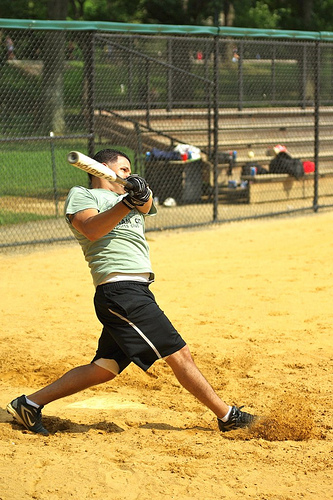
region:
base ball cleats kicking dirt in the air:
[214, 401, 279, 440]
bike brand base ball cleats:
[8, 394, 57, 437]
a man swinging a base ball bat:
[4, 142, 296, 442]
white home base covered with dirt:
[66, 385, 154, 417]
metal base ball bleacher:
[81, 88, 332, 211]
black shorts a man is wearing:
[80, 277, 217, 380]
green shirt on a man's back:
[64, 185, 174, 279]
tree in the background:
[38, 0, 83, 147]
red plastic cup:
[185, 150, 188, 158]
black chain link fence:
[0, 6, 331, 254]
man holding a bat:
[58, 144, 174, 315]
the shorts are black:
[44, 257, 245, 430]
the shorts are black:
[65, 281, 196, 388]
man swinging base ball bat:
[0, 143, 266, 447]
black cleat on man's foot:
[216, 405, 260, 429]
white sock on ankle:
[215, 403, 234, 422]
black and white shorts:
[81, 278, 181, 374]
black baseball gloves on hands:
[118, 170, 151, 210]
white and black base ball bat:
[71, 149, 130, 188]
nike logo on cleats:
[22, 411, 37, 427]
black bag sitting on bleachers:
[271, 150, 302, 181]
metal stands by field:
[191, 99, 321, 170]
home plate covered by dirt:
[67, 386, 146, 419]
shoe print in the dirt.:
[91, 468, 142, 487]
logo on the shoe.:
[25, 413, 35, 428]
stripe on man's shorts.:
[119, 313, 158, 355]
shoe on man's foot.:
[221, 405, 264, 430]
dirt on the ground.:
[187, 242, 223, 260]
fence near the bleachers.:
[235, 93, 274, 119]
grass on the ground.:
[20, 163, 42, 177]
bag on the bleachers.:
[275, 155, 300, 177]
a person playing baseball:
[38, 150, 224, 352]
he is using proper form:
[10, 387, 261, 450]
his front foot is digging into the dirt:
[208, 395, 285, 445]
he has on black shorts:
[85, 283, 210, 384]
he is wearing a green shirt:
[59, 179, 179, 284]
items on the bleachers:
[157, 118, 331, 210]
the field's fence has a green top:
[42, 19, 312, 109]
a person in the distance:
[3, 36, 24, 62]